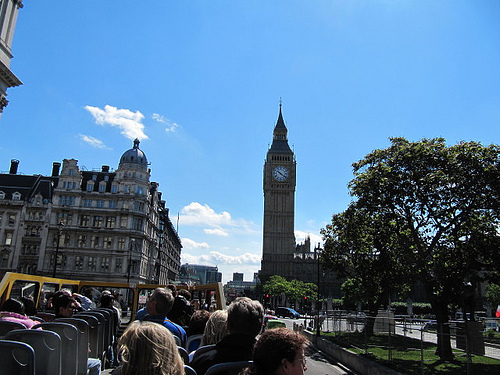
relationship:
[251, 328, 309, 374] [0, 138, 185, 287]
person walking near top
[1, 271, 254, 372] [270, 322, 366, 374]
tour bus driving down street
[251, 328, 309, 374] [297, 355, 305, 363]
person wearing glasses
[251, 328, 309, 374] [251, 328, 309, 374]
person of a person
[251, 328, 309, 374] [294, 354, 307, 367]
person wearing glasses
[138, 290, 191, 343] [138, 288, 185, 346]
man shows back of man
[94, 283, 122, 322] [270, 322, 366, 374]
person walking down a street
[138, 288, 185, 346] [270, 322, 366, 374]
man walking down a street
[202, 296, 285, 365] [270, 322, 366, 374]
person walking down a street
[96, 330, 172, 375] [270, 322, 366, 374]
person walking down a street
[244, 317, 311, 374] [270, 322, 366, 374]
person walking down a street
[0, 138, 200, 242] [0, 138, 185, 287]
top of a top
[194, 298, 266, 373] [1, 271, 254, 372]
person in tour bus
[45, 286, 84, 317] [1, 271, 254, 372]
tourist in tour bus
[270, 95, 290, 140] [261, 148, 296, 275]
top of pillar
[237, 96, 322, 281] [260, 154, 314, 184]
pillar with clock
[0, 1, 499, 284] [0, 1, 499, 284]
view of view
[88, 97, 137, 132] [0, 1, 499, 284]
clouds in view